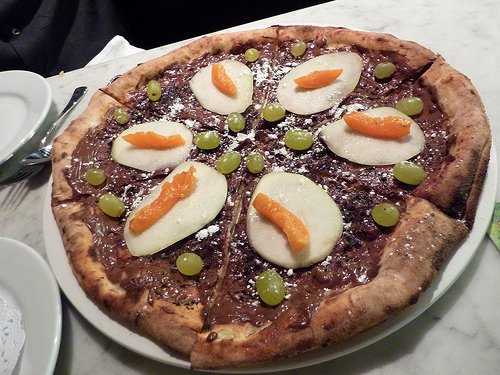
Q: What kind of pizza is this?
A: Fruit pizza.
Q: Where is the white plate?
A: Under the pizza.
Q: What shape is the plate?
A: Round.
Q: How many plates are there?
A: Three.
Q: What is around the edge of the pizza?
A: Crust.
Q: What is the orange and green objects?
A: Fruit.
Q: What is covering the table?
A: A tablecloth.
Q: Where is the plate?
A: On the table.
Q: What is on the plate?
A: Dessert pizza.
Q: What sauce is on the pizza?
A: Chocolate.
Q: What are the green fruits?
A: Grapes.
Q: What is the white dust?
A: Powdered sugar.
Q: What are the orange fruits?
A: Peaches.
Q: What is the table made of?
A: Marble.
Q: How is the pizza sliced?
A: In triangles.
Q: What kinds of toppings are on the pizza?
A: Chocolate and fruit.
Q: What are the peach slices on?
A: Pear slices.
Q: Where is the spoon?
A: Behind the plate.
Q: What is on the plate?
A: Food.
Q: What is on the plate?
A: Dessert.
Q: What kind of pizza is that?
A: Chocolate and fruit.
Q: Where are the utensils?
A: Beside the plate.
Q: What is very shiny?
A: Spoon.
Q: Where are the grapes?
A: On top of the pizza.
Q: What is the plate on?
A: Counter.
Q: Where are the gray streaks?
A: On the counter.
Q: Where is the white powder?
A: On top of the pizza.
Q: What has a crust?
A: Pizza.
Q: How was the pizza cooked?
A: Baked.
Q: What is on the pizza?
A: Orange.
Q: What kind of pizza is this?
A: Dessert.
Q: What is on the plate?
A: Pizza.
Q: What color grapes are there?
A: Green.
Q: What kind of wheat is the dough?
A: Whole wheat.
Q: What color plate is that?
A: White.